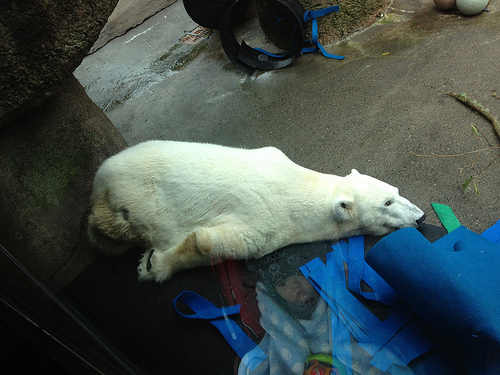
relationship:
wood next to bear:
[1, 241, 148, 374] [86, 138, 428, 286]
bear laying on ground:
[86, 138, 428, 286] [57, 0, 499, 374]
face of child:
[275, 270, 318, 306] [237, 242, 412, 374]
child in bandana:
[237, 242, 412, 374] [255, 241, 316, 287]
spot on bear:
[174, 228, 212, 264] [86, 138, 428, 286]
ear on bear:
[333, 197, 356, 220] [86, 138, 428, 286]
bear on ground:
[86, 138, 428, 286] [57, 0, 499, 374]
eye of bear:
[384, 198, 394, 207] [86, 138, 428, 286]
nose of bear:
[415, 212, 426, 224] [86, 138, 428, 286]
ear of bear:
[349, 169, 360, 176] [86, 138, 428, 286]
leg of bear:
[136, 223, 287, 283] [86, 138, 428, 286]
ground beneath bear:
[57, 0, 499, 374] [86, 138, 428, 286]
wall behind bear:
[86, 0, 184, 56] [86, 138, 428, 286]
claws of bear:
[135, 249, 147, 282] [86, 138, 428, 286]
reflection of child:
[212, 230, 414, 374] [237, 242, 412, 374]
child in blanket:
[237, 242, 412, 374] [238, 281, 414, 374]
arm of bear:
[136, 223, 287, 283] [86, 138, 428, 286]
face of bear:
[370, 177, 427, 235] [86, 138, 428, 286]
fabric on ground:
[298, 215, 500, 375] [57, 0, 499, 374]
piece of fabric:
[358, 304, 416, 357] [298, 215, 500, 375]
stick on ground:
[445, 89, 500, 144] [57, 0, 499, 374]